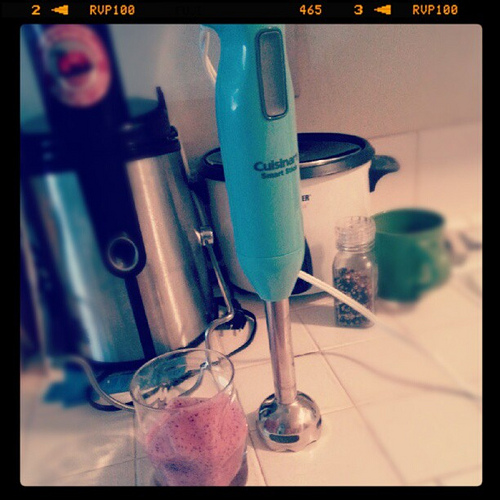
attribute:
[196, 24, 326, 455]
immerision blender — teal green, turquoise, handheld, blue, stainless steel, electric, cuisinart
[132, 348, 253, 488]
smoothie — pink, lavender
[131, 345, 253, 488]
glass — small, half full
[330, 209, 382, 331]
pepper grinder — plastic, clear, mostly full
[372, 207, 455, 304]
mug — green, blue, ceramic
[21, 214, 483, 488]
kitchen counter — tiled, white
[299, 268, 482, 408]
electrical cord — white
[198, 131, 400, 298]
appliance — small, white, black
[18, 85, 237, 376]
appliance — silver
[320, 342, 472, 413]
ceramic tile — white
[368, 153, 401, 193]
handle — black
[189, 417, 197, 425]
seed — black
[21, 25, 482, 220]
wall — white